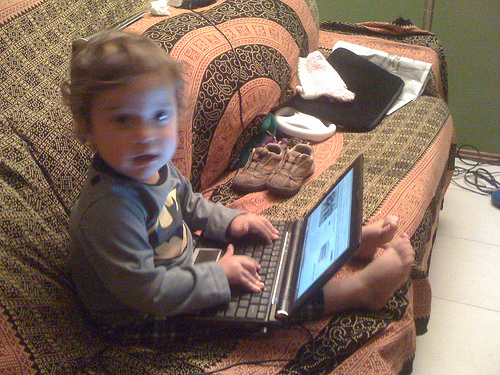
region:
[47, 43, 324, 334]
a little girl with laptop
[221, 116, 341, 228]
shoes on the couch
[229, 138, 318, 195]
brown shoes on the couch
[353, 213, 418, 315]
kid's bare feet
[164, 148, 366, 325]
black laptop on the kid's lap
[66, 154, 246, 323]
gray and yellow batman sweatshirt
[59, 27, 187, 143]
the kid has brown hair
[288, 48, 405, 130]
black laptop cover on the couch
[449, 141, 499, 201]
black power cords on the floor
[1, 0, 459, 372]
brown and pink couch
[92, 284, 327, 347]
plaid pajama pants on the kid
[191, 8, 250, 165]
black power cord on the couch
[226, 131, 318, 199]
the kid's shoes sit on the sofa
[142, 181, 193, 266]
cool Batman logo on the kid's t-shirt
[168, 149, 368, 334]
this tiny child is a pro with his laptop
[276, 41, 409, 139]
laptop case on the sofa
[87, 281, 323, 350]
kid is wearing plaid pants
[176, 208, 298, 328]
the keys on this keyboard are gray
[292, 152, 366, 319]
the laptop is turned on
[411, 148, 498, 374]
this place has a white tile floor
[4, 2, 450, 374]
the sofa is swathed in a sofa cover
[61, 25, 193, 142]
the blurry little child has blond hair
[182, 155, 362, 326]
A laptop is in use.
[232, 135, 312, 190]
A pair of shoes with no feet in them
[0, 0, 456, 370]
A couch has many colors.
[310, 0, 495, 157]
The wallis green.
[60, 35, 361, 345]
A toddler is on a working laptop.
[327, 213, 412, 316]
The feet are bare.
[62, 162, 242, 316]
The gray shirt has a Batman symbol on it.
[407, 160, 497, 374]
The floor is white and has wires on it.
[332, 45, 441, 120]
A newspaper is under a black pillow.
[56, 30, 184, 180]
The child has brown hair and a round face.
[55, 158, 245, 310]
Boy is wearing a shirt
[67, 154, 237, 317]
Boy wearing a shirt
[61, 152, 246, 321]
Boy wearing a gray shirt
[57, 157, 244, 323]
Boy is wearing a gray shirt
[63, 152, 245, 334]
Boy wearing a long sleeved shirt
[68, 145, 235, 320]
Boy is wearing a long sleeved shirt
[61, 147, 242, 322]
Boy wearing a gray long sleeved shirt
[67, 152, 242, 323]
Boy is wearing a gray long sleeved shirt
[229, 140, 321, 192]
Shoes on the couch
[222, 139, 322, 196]
Shoes are on the couch